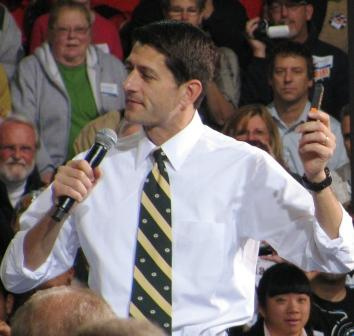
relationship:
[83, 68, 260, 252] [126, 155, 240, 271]
man in shirt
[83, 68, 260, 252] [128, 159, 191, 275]
man in tie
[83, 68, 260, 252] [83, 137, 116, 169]
man with microphone